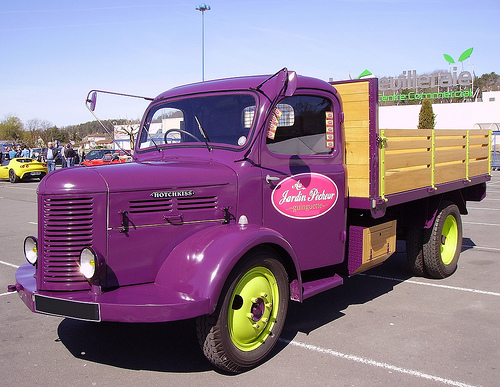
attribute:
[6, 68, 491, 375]
truck — purple, hotchkiss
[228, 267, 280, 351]
hubcap — yellow-green, lemon, green, yellow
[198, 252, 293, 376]
tire — black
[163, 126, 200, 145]
wheel — steering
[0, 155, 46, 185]
car — yellow, sports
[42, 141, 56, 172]
man — standing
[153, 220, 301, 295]
fender — purple, rounded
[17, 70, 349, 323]
paint — purple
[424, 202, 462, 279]
wheel — yellow, lime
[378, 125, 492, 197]
bed — brown, wooden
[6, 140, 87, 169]
people — gathering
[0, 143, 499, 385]
lot — parking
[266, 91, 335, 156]
window — side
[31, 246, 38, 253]
bulb — yellow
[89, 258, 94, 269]
bulb — yellow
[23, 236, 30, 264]
rim — dark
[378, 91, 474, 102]
sign — advertising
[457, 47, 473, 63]
highlight — green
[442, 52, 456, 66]
highlight — green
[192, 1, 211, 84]
streetlight — tall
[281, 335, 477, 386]
line — white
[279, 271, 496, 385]
space — parking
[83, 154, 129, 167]
car — red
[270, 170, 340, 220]
logo — pink, white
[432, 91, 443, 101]
letter — green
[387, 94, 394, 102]
letter — green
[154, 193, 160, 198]
letter — grey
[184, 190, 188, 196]
letter — grey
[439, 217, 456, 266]
hubcap — yellow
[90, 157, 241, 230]
door — engine